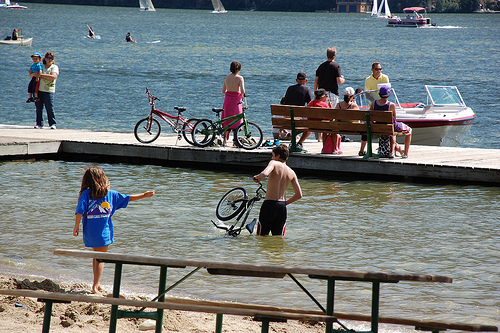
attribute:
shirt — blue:
[79, 188, 133, 246]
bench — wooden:
[247, 54, 469, 179]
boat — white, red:
[381, 3, 440, 30]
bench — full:
[271, 102, 402, 159]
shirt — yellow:
[363, 72, 390, 92]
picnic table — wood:
[2, 242, 498, 331]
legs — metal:
[37, 276, 384, 331]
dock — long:
[71, 95, 498, 218]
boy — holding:
[252, 144, 303, 236]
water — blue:
[4, 0, 494, 319]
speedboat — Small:
[188, 35, 480, 169]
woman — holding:
[31, 49, 59, 133]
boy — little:
[24, 49, 44, 108]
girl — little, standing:
[72, 164, 160, 289]